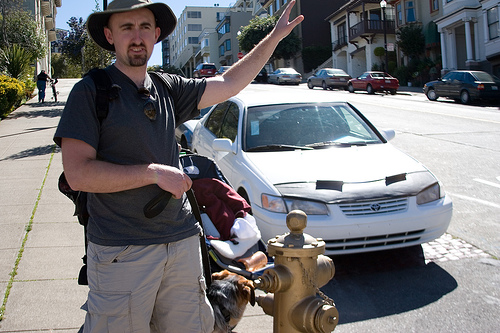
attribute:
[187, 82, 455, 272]
car — parked, white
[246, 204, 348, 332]
hydrant — dull yellow, yellow, gold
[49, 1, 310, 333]
man — waving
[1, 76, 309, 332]
sidewalk — paved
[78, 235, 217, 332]
pants — light beige, tan, khaki, cargo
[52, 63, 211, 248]
t-shirt — dark grey, charcoal, grey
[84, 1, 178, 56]
hat — large, grey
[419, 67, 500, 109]
car — parked, black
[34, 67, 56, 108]
man — pushing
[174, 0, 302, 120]
arm — extended, out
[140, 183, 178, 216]
leash — black